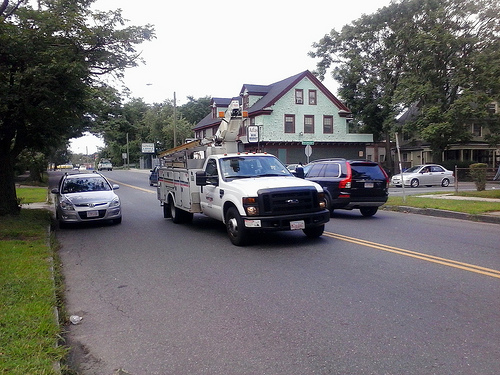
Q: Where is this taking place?
A: Outdoors.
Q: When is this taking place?
A: Daytime.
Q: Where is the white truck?
A: Street.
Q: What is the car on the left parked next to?
A: Sidewalk.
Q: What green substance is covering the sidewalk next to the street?
A: Grass.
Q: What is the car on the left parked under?
A: Tree.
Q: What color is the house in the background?
A: Mint green.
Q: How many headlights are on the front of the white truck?
A: Two.